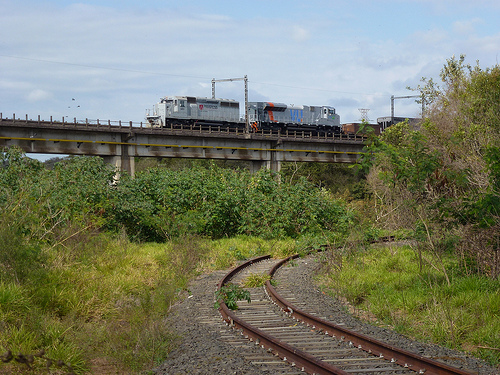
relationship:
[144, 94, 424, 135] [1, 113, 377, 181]
train on bridge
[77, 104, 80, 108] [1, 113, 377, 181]
bird above bridge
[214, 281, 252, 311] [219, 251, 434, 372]
weed on railroad track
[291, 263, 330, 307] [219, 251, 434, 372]
gravel next to railroad track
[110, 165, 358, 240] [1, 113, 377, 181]
bushes under bridge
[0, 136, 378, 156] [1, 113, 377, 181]
yellow line on bridge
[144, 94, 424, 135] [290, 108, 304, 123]
train has blue marks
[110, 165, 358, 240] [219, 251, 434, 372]
bushes behind railroad track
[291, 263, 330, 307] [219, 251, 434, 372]
gravel beside railroad track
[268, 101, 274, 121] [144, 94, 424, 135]
red stripe on train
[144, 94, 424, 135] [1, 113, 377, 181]
train crossing bridge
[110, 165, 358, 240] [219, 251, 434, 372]
bushes by railroad track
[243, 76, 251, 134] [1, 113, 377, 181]
height pole on bridge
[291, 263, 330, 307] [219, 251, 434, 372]
gravel by railroad track